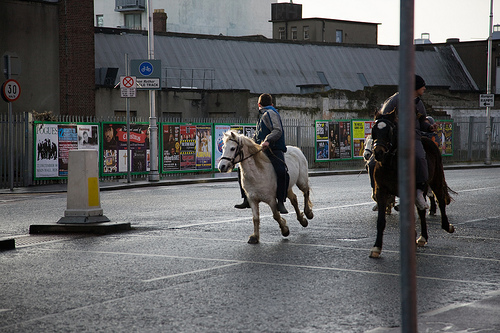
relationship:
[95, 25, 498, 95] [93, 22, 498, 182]
awning of building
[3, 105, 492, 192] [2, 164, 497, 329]
fence on side of road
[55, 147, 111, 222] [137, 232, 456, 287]
statue in median of road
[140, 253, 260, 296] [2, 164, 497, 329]
line painted on road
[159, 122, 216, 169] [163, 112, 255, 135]
signs are on fence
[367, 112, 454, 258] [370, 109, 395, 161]
horse has head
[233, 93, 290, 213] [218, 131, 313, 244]
person riding horse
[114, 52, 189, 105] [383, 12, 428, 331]
sign on a pole